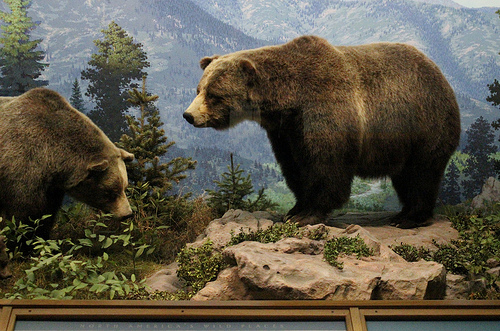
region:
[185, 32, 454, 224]
the big brown bear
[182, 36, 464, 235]
the big bear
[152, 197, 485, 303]
the big rock under the bear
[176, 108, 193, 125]
the bear's nose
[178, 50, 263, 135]
the bear's head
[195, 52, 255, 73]
the ears on the bears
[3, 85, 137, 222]
the bear on the left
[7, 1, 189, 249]
the trees in the back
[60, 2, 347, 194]
the mountains in the back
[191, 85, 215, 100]
the bear's eyes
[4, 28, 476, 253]
bears on the rocks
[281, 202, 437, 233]
the paw of the bear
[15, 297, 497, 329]
the placard for the exhibit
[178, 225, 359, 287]
leaves in between the rocks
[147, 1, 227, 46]
trees on the mountain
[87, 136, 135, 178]
the ears of the bear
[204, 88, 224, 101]
the eye of the bear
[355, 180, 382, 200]
a river under the bear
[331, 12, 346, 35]
the grassy hillside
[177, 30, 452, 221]
a brown bear on four legs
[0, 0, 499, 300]
an image of two grizzly bears foraging in the woods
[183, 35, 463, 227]
a museums taxidermy of a grizzly bear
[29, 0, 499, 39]
tall mountains in the background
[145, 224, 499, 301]
mountain rocks on a cliff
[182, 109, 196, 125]
the grizzly bears nose is black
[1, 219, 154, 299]
wild flowers growing in the field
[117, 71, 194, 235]
a pine tree growing in the field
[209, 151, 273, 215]
a young pine tree behind the rocks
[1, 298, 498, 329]
a wooden frame window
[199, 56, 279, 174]
a reflection on the glass window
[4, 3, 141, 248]
Brown bear on left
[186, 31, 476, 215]
Brown bear on right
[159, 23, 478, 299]
Bear standing on rocks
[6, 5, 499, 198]
Mountains in background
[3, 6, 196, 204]
Green pine trees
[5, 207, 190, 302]
Shrubs by rocks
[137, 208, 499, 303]
Ground cover growing on rocks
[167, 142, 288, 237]
Pine trees below rocks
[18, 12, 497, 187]
Trees on the mountains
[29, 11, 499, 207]
Foggy looking mountains in background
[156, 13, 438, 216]
a bear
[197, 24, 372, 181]
a bear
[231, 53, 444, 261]
a bear